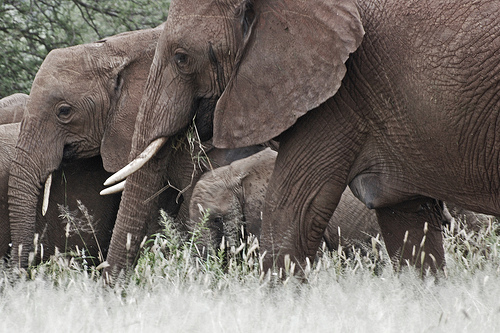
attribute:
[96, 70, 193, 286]
trunk — long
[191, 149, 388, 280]
baby elephant — SMALL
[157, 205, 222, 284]
grass — wispy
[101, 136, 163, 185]
tusk — pair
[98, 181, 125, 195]
tusk — pair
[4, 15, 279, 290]
elephant — ADULT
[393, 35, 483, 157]
skin — wrinkled, gray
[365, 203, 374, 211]
nipple — VERY LARGE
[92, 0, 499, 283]
elephant — large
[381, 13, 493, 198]
skin elephant — wrinkled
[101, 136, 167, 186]
tusks — white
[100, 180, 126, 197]
tusks — white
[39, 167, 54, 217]
tusks — white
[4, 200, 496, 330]
grass — tall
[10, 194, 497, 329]
plants — few, fern like